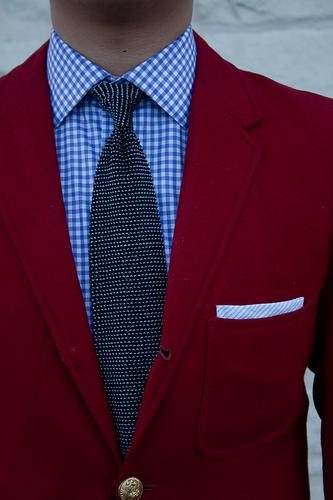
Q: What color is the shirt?
A: Blue and white.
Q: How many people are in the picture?
A: One.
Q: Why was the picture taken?
A: For a fashion magazine.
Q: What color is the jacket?
A: Red.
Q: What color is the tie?
A: Black with white dots.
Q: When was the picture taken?
A: In the daytime.